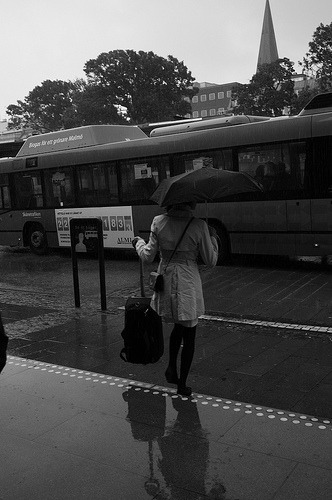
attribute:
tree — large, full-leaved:
[10, 44, 194, 130]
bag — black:
[119, 296, 164, 364]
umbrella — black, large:
[147, 166, 263, 208]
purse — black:
[146, 271, 165, 294]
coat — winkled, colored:
[134, 206, 220, 322]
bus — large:
[1, 93, 331, 267]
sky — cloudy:
[1, 1, 259, 48]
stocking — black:
[179, 325, 196, 385]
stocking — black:
[166, 323, 181, 367]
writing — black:
[115, 234, 133, 246]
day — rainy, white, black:
[1, 2, 331, 131]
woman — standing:
[129, 201, 221, 396]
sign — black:
[69, 217, 107, 311]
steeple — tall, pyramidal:
[255, 0, 279, 71]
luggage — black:
[118, 296, 165, 364]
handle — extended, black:
[136, 258, 145, 294]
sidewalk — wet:
[1, 369, 330, 500]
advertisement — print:
[55, 206, 136, 250]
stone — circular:
[315, 423, 329, 431]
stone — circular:
[266, 412, 276, 420]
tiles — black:
[205, 268, 329, 314]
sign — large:
[54, 206, 133, 248]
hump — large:
[14, 113, 150, 157]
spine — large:
[160, 171, 200, 206]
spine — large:
[215, 167, 262, 192]